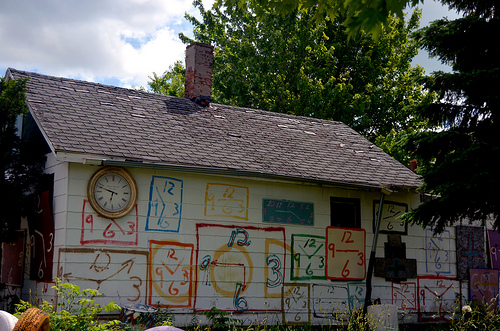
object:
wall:
[70, 161, 496, 319]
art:
[78, 167, 479, 309]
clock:
[91, 164, 140, 219]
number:
[341, 231, 357, 244]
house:
[4, 65, 446, 322]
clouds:
[0, 0, 200, 103]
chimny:
[183, 40, 217, 105]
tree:
[151, 0, 432, 169]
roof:
[10, 65, 421, 186]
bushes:
[9, 277, 125, 331]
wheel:
[14, 305, 48, 331]